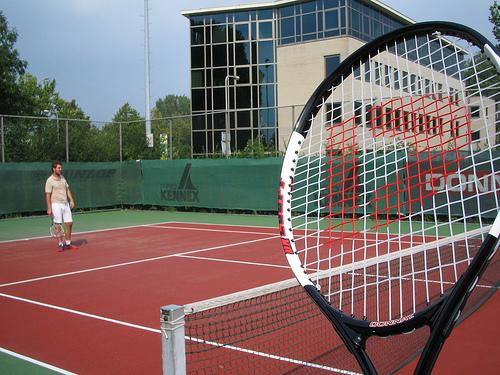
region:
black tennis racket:
[279, 21, 497, 372]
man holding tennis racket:
[42, 160, 77, 252]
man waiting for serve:
[41, 162, 79, 254]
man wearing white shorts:
[43, 163, 78, 252]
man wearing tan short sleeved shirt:
[42, 162, 78, 250]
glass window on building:
[213, 44, 227, 67]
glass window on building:
[277, 15, 293, 34]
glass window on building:
[322, 7, 341, 30]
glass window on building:
[303, 11, 317, 31]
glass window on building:
[237, 110, 253, 126]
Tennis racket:
[253, 30, 486, 361]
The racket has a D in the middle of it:
[275, 65, 498, 335]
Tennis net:
[162, 288, 305, 371]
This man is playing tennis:
[28, 136, 108, 252]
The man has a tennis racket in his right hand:
[36, 153, 86, 252]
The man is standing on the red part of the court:
[36, 147, 98, 252]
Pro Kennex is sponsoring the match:
[146, 153, 205, 207]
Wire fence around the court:
[27, 108, 277, 157]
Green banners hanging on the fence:
[82, 156, 272, 208]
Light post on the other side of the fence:
[212, 60, 249, 146]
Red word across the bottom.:
[366, 315, 430, 327]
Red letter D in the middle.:
[332, 102, 444, 229]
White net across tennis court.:
[163, 297, 325, 360]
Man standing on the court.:
[39, 153, 84, 253]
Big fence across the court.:
[31, 101, 242, 249]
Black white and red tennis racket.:
[299, 13, 490, 329]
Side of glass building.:
[180, 2, 360, 158]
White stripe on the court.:
[8, 333, 70, 372]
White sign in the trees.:
[152, 125, 174, 157]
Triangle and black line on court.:
[176, 160, 200, 192]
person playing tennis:
[41, 160, 82, 245]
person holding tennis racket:
[40, 145, 80, 256]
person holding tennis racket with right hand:
[41, 160, 86, 257]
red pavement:
[72, 275, 197, 297]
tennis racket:
[285, 35, 490, 370]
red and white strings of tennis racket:
[315, 75, 485, 235]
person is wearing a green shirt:
[39, 160, 81, 207]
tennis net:
[181, 312, 278, 370]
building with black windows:
[188, 14, 270, 132]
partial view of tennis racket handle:
[302, 310, 494, 374]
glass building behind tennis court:
[187, 3, 467, 158]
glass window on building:
[234, 42, 250, 65]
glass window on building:
[257, 40, 273, 63]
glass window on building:
[235, 127, 250, 149]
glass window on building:
[190, 130, 208, 154]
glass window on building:
[190, 112, 204, 128]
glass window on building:
[191, 88, 203, 111]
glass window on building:
[191, 43, 203, 67]